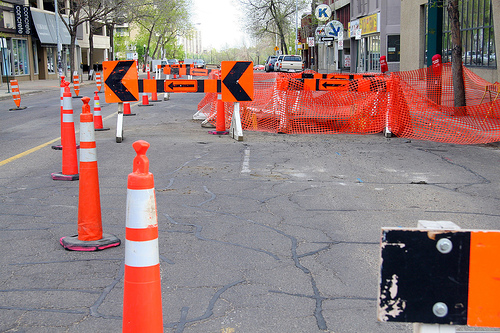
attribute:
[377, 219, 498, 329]
sign — black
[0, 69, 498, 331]
road — under construction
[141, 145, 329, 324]
cracks — patched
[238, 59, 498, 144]
fencing — orange, construction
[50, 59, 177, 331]
road sign — white, orange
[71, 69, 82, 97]
sign — orange, white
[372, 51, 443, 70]
bags — red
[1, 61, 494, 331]
city street — under repair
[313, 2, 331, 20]
signs — white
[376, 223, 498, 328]
banner — orange, black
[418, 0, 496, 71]
window — green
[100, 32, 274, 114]
sign — orange, white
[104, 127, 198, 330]
cones — orange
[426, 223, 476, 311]
bolts — silver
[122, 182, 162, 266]
stripes — white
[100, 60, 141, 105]
detour sign — orange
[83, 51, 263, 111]
sign — white, orange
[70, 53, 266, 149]
sign — orange, white